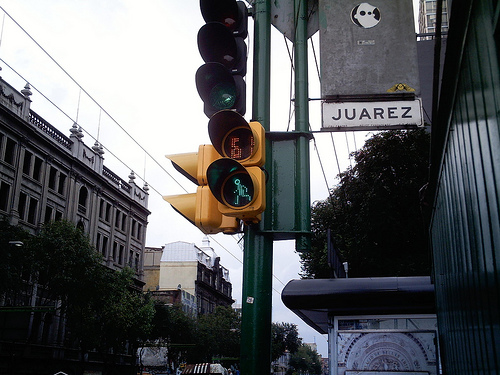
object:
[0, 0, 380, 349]
sky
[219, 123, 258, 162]
light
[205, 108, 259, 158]
cover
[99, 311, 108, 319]
leaf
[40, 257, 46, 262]
leaf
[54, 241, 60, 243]
leaf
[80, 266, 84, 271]
leaf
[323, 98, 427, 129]
sign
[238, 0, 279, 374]
pole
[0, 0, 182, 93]
clouds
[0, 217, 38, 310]
trees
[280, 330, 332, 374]
man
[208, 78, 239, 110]
light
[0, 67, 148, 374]
building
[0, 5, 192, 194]
power line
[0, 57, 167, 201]
power line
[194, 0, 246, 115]
traffic light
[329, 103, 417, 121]
writings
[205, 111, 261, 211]
traffic light